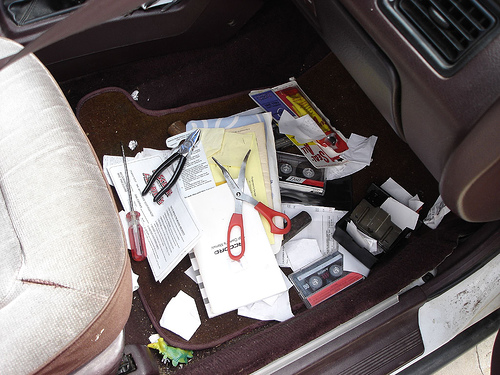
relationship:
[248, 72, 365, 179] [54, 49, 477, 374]
paper on floor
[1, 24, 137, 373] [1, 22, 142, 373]
seat on car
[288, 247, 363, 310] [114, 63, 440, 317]
cassette tape on floor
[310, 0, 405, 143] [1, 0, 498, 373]
jockey box in car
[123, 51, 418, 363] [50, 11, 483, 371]
trash covering floorboard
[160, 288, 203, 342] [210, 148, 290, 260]
paper covered by scissors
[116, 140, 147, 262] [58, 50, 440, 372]
screwdriver on floor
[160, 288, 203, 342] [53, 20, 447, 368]
paper on floor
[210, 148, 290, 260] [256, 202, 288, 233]
scissors with handle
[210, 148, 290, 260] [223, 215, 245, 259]
scissors with handle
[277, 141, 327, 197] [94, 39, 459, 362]
cassette tape lying on floor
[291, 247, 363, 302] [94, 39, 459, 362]
cassette tape lying on floor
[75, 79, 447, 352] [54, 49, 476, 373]
carpet on floor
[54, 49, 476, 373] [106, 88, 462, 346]
floor covered in junk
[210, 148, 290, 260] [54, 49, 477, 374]
scissors on floor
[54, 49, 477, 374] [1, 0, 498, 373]
floor of car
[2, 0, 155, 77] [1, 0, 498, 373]
seat belt in car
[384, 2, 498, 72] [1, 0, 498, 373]
air vent in car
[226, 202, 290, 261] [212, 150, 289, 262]
handle of scissor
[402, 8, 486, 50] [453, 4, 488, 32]
air conditioner in vent